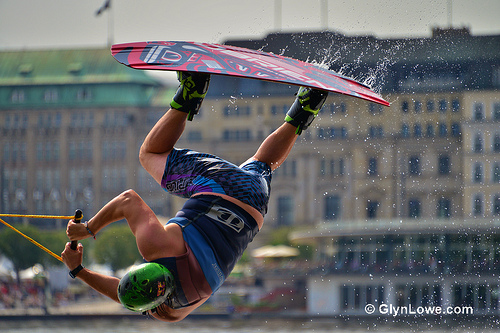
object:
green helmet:
[117, 262, 176, 313]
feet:
[175, 70, 210, 85]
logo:
[205, 205, 245, 233]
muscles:
[119, 187, 167, 256]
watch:
[69, 264, 83, 279]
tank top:
[161, 187, 260, 311]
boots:
[166, 70, 209, 122]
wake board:
[109, 40, 390, 108]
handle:
[70, 209, 83, 248]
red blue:
[111, 38, 391, 135]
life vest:
[143, 192, 264, 309]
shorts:
[160, 148, 271, 218]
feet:
[295, 86, 330, 105]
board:
[109, 41, 391, 106]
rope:
[0, 212, 74, 261]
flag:
[92, 0, 113, 17]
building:
[0, 26, 498, 316]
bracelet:
[85, 221, 96, 240]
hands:
[65, 219, 88, 241]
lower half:
[137, 72, 327, 209]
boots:
[282, 85, 329, 134]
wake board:
[128, 26, 403, 117]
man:
[60, 70, 330, 322]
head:
[116, 262, 175, 313]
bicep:
[123, 201, 154, 234]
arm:
[88, 189, 166, 255]